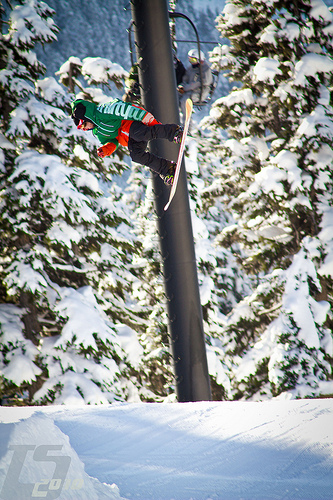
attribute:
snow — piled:
[19, 401, 116, 495]